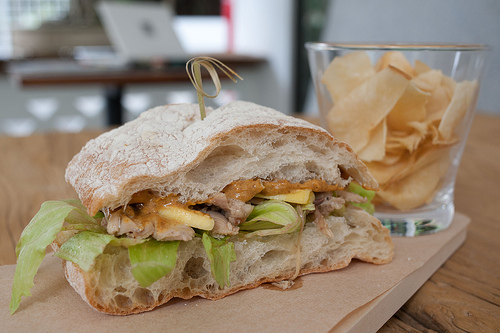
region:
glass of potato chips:
[348, 45, 463, 223]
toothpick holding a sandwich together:
[185, 53, 245, 119]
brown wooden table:
[444, 273, 495, 324]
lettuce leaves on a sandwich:
[23, 198, 100, 253]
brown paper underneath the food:
[200, 303, 341, 318]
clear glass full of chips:
[354, 42, 471, 217]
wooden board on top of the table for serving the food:
[363, 301, 401, 319]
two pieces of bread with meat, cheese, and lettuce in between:
[103, 135, 330, 259]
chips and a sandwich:
[51, 67, 468, 267]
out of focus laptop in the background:
[75, 5, 186, 64]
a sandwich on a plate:
[10, 8, 421, 331]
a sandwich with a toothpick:
[48, 25, 433, 330]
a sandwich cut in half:
[47, 18, 412, 330]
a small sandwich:
[48, 11, 449, 301]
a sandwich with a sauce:
[42, 6, 479, 306]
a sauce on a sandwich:
[76, 68, 463, 331]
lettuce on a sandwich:
[68, 59, 498, 298]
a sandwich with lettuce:
[39, 37, 469, 319]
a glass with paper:
[289, 2, 498, 205]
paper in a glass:
[304, 13, 499, 222]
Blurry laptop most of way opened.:
[76, 0, 186, 65]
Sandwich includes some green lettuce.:
[13, 105, 393, 314]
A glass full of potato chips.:
[307, 42, 493, 234]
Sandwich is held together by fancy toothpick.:
[4, 56, 394, 316]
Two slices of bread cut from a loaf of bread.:
[63, 102, 394, 317]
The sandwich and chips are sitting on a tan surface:
[1, 42, 482, 329]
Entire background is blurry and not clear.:
[0, 0, 498, 140]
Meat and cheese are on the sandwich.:
[84, 176, 368, 246]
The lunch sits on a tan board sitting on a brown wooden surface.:
[0, 42, 499, 331]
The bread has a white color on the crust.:
[63, 100, 368, 214]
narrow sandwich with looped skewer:
[12, 45, 397, 323]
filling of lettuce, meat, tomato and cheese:
[10, 171, 375, 261]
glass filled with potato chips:
[305, 30, 485, 232]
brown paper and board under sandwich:
[12, 206, 474, 322]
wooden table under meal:
[1, 110, 491, 321]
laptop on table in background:
[5, 2, 195, 122]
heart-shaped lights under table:
[10, 86, 235, 126]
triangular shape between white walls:
[267, 1, 337, 106]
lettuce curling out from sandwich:
[0, 200, 231, 311]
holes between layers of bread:
[85, 138, 371, 308]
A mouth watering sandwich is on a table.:
[7, 102, 394, 316]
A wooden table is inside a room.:
[0, 112, 498, 332]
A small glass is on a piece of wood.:
[302, 41, 489, 234]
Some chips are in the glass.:
[320, 49, 477, 216]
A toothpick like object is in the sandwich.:
[184, 55, 243, 119]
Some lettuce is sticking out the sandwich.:
[6, 199, 111, 317]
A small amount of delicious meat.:
[107, 212, 151, 237]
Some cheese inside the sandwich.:
[159, 205, 213, 231]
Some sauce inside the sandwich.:
[222, 178, 338, 203]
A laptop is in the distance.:
[88, 2, 189, 71]